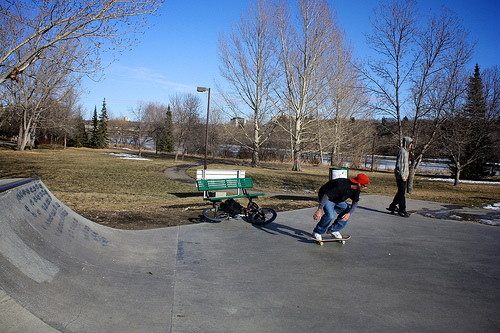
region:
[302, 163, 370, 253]
the man is skateboarding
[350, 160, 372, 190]
man's hat is red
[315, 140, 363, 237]
man is bending down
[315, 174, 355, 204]
man's shirt is black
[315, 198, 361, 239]
man is wearing blue jeans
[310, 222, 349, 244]
man's shoes are white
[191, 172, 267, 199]
the bench is green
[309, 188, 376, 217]
shirt underneath is gray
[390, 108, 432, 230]
man is walking in background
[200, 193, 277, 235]
bicycle laying on ground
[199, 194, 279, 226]
A bicycle on the ground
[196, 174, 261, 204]
A green bench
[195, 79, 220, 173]
A tall street light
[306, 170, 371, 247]
A man riding a skateboard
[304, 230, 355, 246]
A skateboard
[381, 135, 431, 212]
A man in a grey hoodie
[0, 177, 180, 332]
A quarter pipe ramp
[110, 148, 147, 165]
some snow on the ground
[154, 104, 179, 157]
A tall pine tree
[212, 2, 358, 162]
some large, leafless trees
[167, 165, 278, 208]
The bench is green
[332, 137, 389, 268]
the man with a red hat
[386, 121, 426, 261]
a man wearing a hoodie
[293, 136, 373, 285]
a man on a skateboard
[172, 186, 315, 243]
a bike laying near the bench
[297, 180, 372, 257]
skater wearing blue jeans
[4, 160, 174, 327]
ramp for the skateboarder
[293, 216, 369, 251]
skateboard being used by a man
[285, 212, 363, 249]
white shoes worn by the skater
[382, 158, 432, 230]
black jeans on man that is walking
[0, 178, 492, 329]
a cement skateboarding ramp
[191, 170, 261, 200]
a green bench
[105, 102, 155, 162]
snow on the ground near a tree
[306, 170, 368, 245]
man crouching down while on a skateboard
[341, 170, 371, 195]
man wearing his red cap backwards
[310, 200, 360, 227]
man's hands are down near his knees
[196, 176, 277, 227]
bicycle on the ground near bench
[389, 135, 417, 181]
man wearing a grey jacket with the hood up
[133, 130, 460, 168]
snow covered surface at some distance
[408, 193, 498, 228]
slush and water on cement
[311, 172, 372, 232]
this is a man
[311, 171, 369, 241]
the man is skating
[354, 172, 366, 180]
he is wearing a cap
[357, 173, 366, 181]
the cap is red in color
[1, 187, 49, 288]
the path is curved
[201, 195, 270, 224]
this is a bike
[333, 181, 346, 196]
the t shirt is black in color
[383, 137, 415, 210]
the boy is standing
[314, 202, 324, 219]
this is the hand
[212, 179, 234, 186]
the bench is green in color